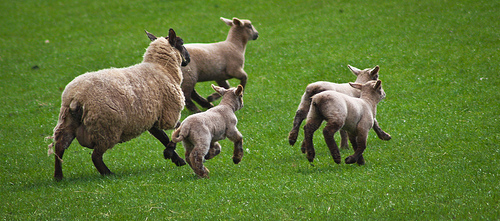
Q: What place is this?
A: It is a field.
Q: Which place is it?
A: It is a field.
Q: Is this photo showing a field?
A: Yes, it is showing a field.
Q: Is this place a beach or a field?
A: It is a field.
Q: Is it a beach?
A: No, it is a field.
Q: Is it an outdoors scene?
A: Yes, it is outdoors.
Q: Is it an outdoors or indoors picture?
A: It is outdoors.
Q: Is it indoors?
A: No, it is outdoors.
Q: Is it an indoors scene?
A: No, it is outdoors.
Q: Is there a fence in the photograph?
A: No, there are no fences.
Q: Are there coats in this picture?
A: Yes, there is a coat.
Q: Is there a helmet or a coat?
A: Yes, there is a coat.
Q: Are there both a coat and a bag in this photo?
A: No, there is a coat but no bags.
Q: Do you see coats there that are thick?
A: Yes, there is a thick coat.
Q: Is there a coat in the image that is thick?
A: Yes, there is a coat that is thick.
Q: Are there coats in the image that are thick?
A: Yes, there is a coat that is thick.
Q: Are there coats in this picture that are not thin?
A: Yes, there is a thick coat.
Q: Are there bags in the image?
A: No, there are no bags.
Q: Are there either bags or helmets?
A: No, there are no bags or helmets.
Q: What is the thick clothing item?
A: The clothing item is a coat.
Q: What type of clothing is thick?
A: The clothing is a coat.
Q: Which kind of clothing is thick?
A: The clothing is a coat.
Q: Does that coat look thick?
A: Yes, the coat is thick.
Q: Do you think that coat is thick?
A: Yes, the coat is thick.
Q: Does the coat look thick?
A: Yes, the coat is thick.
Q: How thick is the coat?
A: The coat is thick.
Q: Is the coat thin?
A: No, the coat is thick.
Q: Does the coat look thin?
A: No, the coat is thick.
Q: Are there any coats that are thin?
A: No, there is a coat but it is thick.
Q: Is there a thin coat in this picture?
A: No, there is a coat but it is thick.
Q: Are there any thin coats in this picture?
A: No, there is a coat but it is thick.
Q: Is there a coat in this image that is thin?
A: No, there is a coat but it is thick.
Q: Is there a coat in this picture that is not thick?
A: No, there is a coat but it is thick.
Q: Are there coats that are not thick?
A: No, there is a coat but it is thick.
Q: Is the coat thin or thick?
A: The coat is thick.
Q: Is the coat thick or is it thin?
A: The coat is thick.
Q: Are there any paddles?
A: No, there are no paddles.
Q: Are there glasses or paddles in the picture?
A: No, there are no paddles or glasses.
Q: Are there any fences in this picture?
A: No, there are no fences.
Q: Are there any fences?
A: No, there are no fences.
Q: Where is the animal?
A: The animal is on the grass.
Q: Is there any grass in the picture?
A: Yes, there is grass.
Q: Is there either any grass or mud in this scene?
A: Yes, there is grass.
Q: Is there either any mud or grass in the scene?
A: Yes, there is grass.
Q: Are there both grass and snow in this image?
A: No, there is grass but no snow.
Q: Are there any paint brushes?
A: No, there are no paint brushes.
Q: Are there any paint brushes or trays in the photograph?
A: No, there are no paint brushes or trays.